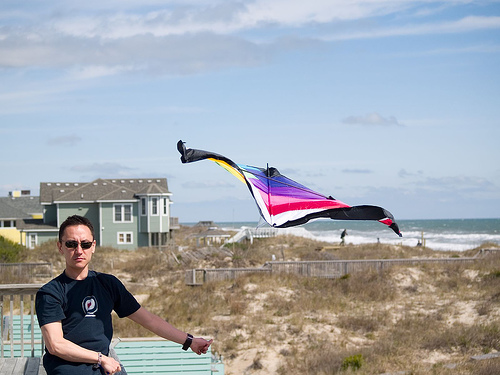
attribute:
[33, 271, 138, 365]
shirt — navy blue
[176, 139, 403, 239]
kite — multi-colored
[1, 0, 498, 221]
sky — partly cloudy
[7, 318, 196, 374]
deck — wooden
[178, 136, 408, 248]
kite — Delta, red, blue, white, yellow, black, pink, lavender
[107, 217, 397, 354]
ocean beach — sandy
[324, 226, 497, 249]
waves — white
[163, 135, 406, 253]
kite — flying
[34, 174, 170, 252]
beachfront home — blue-grey, two-story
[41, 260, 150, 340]
shirt — dark, short sleeve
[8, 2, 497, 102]
clouds — high, white, grey